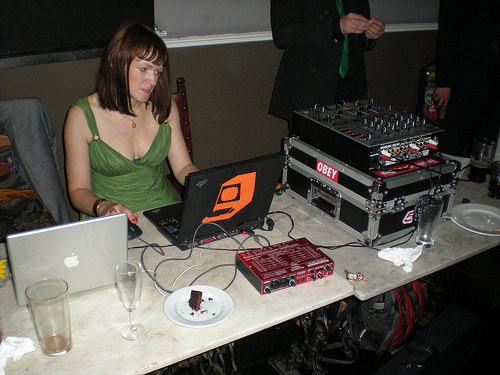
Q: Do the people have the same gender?
A: No, they are both male and female.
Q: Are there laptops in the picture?
A: Yes, there is a laptop.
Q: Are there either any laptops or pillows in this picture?
A: Yes, there is a laptop.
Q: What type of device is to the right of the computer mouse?
A: The device is a laptop.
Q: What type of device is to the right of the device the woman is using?
A: The device is a laptop.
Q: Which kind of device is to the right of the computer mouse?
A: The device is a laptop.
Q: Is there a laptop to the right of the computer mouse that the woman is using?
A: Yes, there is a laptop to the right of the computer mouse.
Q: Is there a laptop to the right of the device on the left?
A: Yes, there is a laptop to the right of the computer mouse.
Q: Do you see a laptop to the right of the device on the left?
A: Yes, there is a laptop to the right of the computer mouse.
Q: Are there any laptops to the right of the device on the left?
A: Yes, there is a laptop to the right of the computer mouse.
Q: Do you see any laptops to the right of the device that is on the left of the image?
A: Yes, there is a laptop to the right of the computer mouse.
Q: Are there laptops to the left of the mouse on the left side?
A: No, the laptop is to the right of the mouse.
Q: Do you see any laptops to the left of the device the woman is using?
A: No, the laptop is to the right of the mouse.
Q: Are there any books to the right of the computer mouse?
A: No, there is a laptop to the right of the computer mouse.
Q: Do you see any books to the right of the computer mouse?
A: No, there is a laptop to the right of the computer mouse.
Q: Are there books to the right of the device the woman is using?
A: No, there is a laptop to the right of the computer mouse.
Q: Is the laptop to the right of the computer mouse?
A: Yes, the laptop is to the right of the computer mouse.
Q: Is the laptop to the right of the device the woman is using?
A: Yes, the laptop is to the right of the computer mouse.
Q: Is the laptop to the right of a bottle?
A: No, the laptop is to the right of the computer mouse.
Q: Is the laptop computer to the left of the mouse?
A: No, the laptop computer is to the right of the mouse.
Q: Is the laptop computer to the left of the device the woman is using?
A: No, the laptop computer is to the right of the mouse.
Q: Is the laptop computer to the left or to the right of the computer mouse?
A: The laptop computer is to the right of the computer mouse.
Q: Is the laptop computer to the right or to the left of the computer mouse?
A: The laptop computer is to the right of the computer mouse.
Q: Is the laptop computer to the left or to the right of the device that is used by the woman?
A: The laptop computer is to the right of the computer mouse.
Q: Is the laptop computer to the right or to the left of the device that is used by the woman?
A: The laptop computer is to the right of the computer mouse.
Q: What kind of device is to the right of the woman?
A: The device is a laptop.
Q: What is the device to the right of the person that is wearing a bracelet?
A: The device is a laptop.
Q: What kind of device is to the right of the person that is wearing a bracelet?
A: The device is a laptop.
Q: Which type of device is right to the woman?
A: The device is a laptop.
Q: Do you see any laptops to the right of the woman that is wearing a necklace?
A: Yes, there is a laptop to the right of the woman.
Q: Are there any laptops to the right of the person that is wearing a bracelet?
A: Yes, there is a laptop to the right of the woman.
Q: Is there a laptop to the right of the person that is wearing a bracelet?
A: Yes, there is a laptop to the right of the woman.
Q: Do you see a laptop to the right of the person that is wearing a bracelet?
A: Yes, there is a laptop to the right of the woman.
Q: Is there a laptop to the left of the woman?
A: No, the laptop is to the right of the woman.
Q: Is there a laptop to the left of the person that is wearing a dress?
A: No, the laptop is to the right of the woman.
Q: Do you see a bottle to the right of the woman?
A: No, there is a laptop to the right of the woman.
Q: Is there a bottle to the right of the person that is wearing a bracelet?
A: No, there is a laptop to the right of the woman.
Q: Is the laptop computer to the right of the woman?
A: Yes, the laptop computer is to the right of the woman.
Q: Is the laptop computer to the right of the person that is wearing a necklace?
A: Yes, the laptop computer is to the right of the woman.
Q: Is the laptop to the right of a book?
A: No, the laptop is to the right of the woman.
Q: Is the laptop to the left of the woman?
A: No, the laptop is to the right of the woman.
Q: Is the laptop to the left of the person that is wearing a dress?
A: No, the laptop is to the right of the woman.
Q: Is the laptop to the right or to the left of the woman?
A: The laptop is to the right of the woman.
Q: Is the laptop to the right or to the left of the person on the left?
A: The laptop is to the right of the woman.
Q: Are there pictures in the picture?
A: No, there are no pictures.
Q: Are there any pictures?
A: No, there are no pictures.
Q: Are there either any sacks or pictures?
A: No, there are no pictures or sacks.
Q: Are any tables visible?
A: Yes, there is a table.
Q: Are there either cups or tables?
A: Yes, there is a table.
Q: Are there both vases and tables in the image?
A: No, there is a table but no vases.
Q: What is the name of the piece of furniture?
A: The piece of furniture is a table.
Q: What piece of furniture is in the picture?
A: The piece of furniture is a table.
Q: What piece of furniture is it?
A: The piece of furniture is a table.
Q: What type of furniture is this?
A: That is a table.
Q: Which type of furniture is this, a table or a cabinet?
A: That is a table.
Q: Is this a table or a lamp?
A: This is a table.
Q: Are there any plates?
A: Yes, there is a plate.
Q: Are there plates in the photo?
A: Yes, there is a plate.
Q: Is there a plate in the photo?
A: Yes, there is a plate.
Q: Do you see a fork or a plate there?
A: Yes, there is a plate.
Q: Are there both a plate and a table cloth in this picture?
A: No, there is a plate but no tablecloths.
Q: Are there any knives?
A: No, there are no knives.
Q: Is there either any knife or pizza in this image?
A: No, there are no knives or pizzas.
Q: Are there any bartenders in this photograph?
A: No, there are no bartenders.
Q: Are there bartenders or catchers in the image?
A: No, there are no bartenders or catchers.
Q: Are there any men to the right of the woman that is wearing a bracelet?
A: Yes, there is a man to the right of the woman.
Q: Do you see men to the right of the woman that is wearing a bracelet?
A: Yes, there is a man to the right of the woman.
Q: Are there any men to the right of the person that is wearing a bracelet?
A: Yes, there is a man to the right of the woman.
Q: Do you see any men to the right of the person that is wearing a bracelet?
A: Yes, there is a man to the right of the woman.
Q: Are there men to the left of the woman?
A: No, the man is to the right of the woman.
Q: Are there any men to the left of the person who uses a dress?
A: No, the man is to the right of the woman.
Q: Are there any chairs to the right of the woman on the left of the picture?
A: No, there is a man to the right of the woman.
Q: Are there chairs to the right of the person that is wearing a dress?
A: No, there is a man to the right of the woman.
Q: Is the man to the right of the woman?
A: Yes, the man is to the right of the woman.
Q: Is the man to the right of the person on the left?
A: Yes, the man is to the right of the woman.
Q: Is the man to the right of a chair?
A: No, the man is to the right of the woman.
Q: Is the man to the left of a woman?
A: No, the man is to the right of a woman.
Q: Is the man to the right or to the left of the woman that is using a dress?
A: The man is to the right of the woman.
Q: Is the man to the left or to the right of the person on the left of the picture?
A: The man is to the right of the woman.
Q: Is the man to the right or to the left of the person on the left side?
A: The man is to the right of the woman.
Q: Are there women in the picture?
A: Yes, there is a woman.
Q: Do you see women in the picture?
A: Yes, there is a woman.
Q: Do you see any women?
A: Yes, there is a woman.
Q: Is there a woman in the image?
A: Yes, there is a woman.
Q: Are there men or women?
A: Yes, there is a woman.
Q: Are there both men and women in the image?
A: Yes, there are both a woman and a man.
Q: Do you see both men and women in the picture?
A: Yes, there are both a woman and a man.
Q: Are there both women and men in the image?
A: Yes, there are both a woman and a man.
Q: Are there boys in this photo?
A: No, there are no boys.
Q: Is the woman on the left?
A: Yes, the woman is on the left of the image.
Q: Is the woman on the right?
A: No, the woman is on the left of the image.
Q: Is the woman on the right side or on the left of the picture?
A: The woman is on the left of the image.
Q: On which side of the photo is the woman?
A: The woman is on the left of the image.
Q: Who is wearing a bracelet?
A: The woman is wearing a bracelet.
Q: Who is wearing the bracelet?
A: The woman is wearing a bracelet.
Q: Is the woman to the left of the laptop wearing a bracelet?
A: Yes, the woman is wearing a bracelet.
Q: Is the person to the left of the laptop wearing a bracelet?
A: Yes, the woman is wearing a bracelet.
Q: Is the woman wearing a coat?
A: No, the woman is wearing a bracelet.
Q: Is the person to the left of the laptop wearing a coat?
A: No, the woman is wearing a bracelet.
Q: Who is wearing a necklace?
A: The woman is wearing a necklace.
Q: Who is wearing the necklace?
A: The woman is wearing a necklace.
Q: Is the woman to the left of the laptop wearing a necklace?
A: Yes, the woman is wearing a necklace.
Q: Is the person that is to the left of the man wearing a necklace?
A: Yes, the woman is wearing a necklace.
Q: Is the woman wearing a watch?
A: No, the woman is wearing a necklace.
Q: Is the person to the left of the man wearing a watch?
A: No, the woman is wearing a necklace.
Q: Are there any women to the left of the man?
A: Yes, there is a woman to the left of the man.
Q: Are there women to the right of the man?
A: No, the woman is to the left of the man.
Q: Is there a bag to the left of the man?
A: No, there is a woman to the left of the man.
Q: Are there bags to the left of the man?
A: No, there is a woman to the left of the man.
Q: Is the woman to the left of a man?
A: Yes, the woman is to the left of a man.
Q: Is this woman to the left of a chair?
A: No, the woman is to the left of a man.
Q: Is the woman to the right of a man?
A: No, the woman is to the left of a man.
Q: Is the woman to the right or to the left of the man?
A: The woman is to the left of the man.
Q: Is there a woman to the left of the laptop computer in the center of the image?
A: Yes, there is a woman to the left of the laptop computer.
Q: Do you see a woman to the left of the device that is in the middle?
A: Yes, there is a woman to the left of the laptop computer.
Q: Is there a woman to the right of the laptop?
A: No, the woman is to the left of the laptop.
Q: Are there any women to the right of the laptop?
A: No, the woman is to the left of the laptop.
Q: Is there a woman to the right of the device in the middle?
A: No, the woman is to the left of the laptop.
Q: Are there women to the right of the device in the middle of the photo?
A: No, the woman is to the left of the laptop.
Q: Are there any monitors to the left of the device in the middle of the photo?
A: No, there is a woman to the left of the laptop.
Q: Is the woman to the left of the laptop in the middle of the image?
A: Yes, the woman is to the left of the laptop.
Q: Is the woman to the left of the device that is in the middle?
A: Yes, the woman is to the left of the laptop.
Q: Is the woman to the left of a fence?
A: No, the woman is to the left of the laptop.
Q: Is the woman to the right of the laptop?
A: No, the woman is to the left of the laptop.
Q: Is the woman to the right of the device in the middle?
A: No, the woman is to the left of the laptop.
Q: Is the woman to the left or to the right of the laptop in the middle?
A: The woman is to the left of the laptop.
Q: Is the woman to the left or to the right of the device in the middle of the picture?
A: The woman is to the left of the laptop.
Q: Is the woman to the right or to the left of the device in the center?
A: The woman is to the left of the laptop.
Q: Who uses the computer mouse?
A: The woman uses the computer mouse.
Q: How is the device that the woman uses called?
A: The device is a computer mouse.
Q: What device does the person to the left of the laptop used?
A: The woman uses a computer mouse.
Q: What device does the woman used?
A: The woman uses a computer mouse.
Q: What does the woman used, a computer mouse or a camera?
A: The woman uses a computer mouse.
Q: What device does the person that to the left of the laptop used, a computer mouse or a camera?
A: The woman uses a computer mouse.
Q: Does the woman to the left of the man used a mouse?
A: Yes, the woman uses a mouse.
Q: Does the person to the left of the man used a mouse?
A: Yes, the woman uses a mouse.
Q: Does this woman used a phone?
A: No, the woman uses a mouse.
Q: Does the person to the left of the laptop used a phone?
A: No, the woman uses a mouse.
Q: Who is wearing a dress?
A: The woman is wearing a dress.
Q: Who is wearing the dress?
A: The woman is wearing a dress.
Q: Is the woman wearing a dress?
A: Yes, the woman is wearing a dress.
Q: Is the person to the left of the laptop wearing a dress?
A: Yes, the woman is wearing a dress.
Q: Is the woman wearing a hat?
A: No, the woman is wearing a dress.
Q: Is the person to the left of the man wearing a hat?
A: No, the woman is wearing a dress.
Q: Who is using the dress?
A: The woman is using the dress.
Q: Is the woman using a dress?
A: Yes, the woman is using a dress.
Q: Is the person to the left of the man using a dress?
A: Yes, the woman is using a dress.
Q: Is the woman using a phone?
A: No, the woman is using a dress.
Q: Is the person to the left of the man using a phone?
A: No, the woman is using a dress.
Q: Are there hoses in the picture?
A: No, there are no hoses.